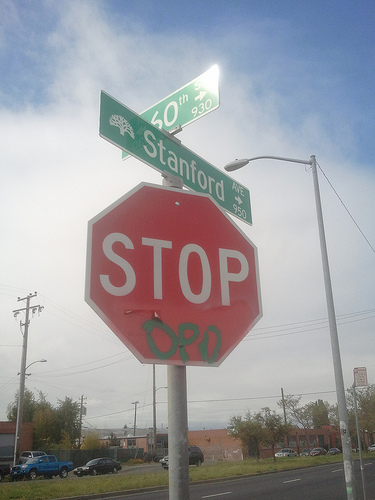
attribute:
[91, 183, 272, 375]
stop sign — below, metal, round, close, here, red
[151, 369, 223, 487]
pole — metal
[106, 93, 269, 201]
sign — wide, long, above, traffic, close, here, green, street, white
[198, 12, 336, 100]
sky — close, here, high, above, bright, white, blue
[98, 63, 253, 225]
signs — street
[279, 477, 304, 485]
line — white, traffic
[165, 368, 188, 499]
pole — metal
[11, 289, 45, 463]
post — tall, electricity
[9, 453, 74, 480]
car — blue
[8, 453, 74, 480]
truck — blue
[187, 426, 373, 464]
building — red, brick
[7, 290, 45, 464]
pole — wood, electrical